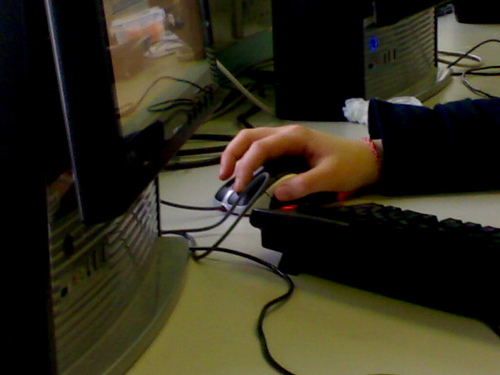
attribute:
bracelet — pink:
[364, 131, 386, 174]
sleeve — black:
[368, 92, 493, 193]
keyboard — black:
[265, 195, 489, 302]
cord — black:
[208, 218, 305, 353]